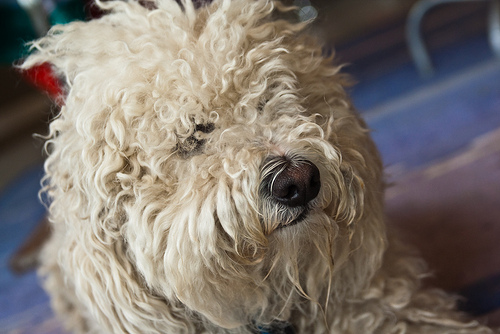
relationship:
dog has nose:
[17, 0, 409, 333] [268, 159, 323, 207]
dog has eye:
[17, 0, 409, 333] [175, 113, 218, 156]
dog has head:
[17, 0, 409, 333] [15, 0, 398, 331]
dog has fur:
[17, 0, 409, 333] [14, 2, 493, 334]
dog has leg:
[17, 0, 409, 333] [318, 275, 495, 333]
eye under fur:
[175, 113, 218, 156] [14, 2, 493, 334]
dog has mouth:
[17, 0, 409, 333] [264, 208, 316, 234]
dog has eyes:
[17, 0, 409, 333] [171, 93, 287, 159]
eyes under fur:
[171, 93, 287, 159] [14, 2, 493, 334]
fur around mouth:
[224, 200, 361, 313] [264, 208, 316, 234]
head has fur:
[15, 0, 398, 331] [17, 0, 390, 327]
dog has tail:
[17, 0, 409, 333] [35, 237, 82, 318]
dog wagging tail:
[17, 0, 409, 333] [35, 237, 82, 318]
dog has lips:
[17, 0, 409, 333] [266, 209, 314, 230]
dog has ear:
[17, 0, 409, 333] [51, 70, 138, 196]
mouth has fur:
[264, 208, 316, 234] [224, 200, 361, 313]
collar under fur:
[136, 279, 325, 333] [14, 2, 493, 334]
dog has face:
[17, 0, 409, 333] [134, 69, 383, 296]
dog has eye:
[17, 0, 409, 333] [255, 94, 275, 113]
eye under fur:
[255, 94, 275, 113] [14, 2, 493, 334]